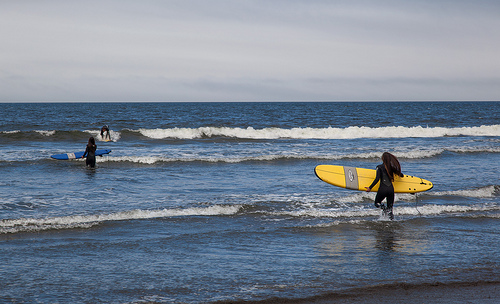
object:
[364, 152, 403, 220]
surfer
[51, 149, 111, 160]
surfboard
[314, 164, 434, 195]
surfboard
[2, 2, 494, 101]
sky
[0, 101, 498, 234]
ocean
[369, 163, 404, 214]
wetsuit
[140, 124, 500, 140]
waves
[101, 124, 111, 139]
surfer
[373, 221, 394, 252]
reflection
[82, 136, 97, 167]
surfer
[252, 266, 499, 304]
beach